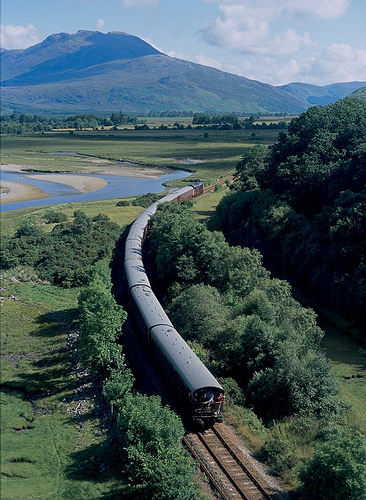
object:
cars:
[123, 181, 225, 431]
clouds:
[1, 21, 31, 46]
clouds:
[199, 4, 310, 60]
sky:
[175, 2, 366, 50]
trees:
[231, 292, 310, 375]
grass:
[1, 396, 168, 500]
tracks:
[184, 425, 274, 499]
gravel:
[62, 323, 101, 433]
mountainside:
[1, 28, 366, 120]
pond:
[0, 151, 197, 212]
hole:
[343, 374, 363, 380]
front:
[186, 386, 225, 429]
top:
[124, 181, 224, 392]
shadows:
[0, 307, 91, 399]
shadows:
[163, 146, 249, 169]